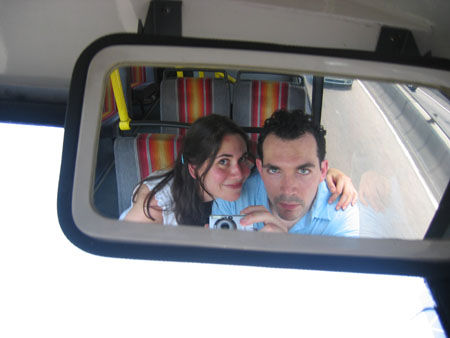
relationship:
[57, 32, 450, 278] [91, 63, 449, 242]
black border around mirror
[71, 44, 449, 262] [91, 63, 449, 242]
gray border around mirror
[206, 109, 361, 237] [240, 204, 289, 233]
man has a left hand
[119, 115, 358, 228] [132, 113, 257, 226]
woman has hair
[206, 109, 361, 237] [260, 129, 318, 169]
man has a high forehead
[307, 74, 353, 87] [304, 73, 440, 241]
vehicle on road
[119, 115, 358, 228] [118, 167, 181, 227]
woman wearing a top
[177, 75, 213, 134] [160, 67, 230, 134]
stripes are on seat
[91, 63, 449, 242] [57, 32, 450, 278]
mirror has a black border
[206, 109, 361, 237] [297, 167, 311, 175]
man has left eye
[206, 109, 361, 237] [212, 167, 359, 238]
man wearing a shirt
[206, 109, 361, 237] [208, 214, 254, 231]
man holding camera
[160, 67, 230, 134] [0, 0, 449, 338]
seat in vehicle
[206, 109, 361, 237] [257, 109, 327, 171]
man has hair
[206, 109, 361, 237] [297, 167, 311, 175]
man has a left eye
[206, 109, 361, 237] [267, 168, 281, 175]
man has a right eye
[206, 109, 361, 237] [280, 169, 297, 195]
man has a nose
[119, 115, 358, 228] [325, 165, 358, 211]
woman has a left hand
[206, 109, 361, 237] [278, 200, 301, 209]
man has a mouth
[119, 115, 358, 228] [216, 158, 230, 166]
woman has a right eye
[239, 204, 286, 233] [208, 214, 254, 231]
fingers on camera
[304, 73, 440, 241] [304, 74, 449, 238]
road outside of window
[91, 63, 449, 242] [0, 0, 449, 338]
mirror on vehicle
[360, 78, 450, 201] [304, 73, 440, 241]
divider on road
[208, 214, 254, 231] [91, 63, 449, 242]
camera reflecting in mirror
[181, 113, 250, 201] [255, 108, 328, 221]
head close to another head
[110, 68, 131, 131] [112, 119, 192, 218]
pole attached to seat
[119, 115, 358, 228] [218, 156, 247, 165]
woman has eyes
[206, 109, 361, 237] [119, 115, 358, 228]
man sitting next to a woman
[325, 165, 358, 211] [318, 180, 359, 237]
left hand on shoulder